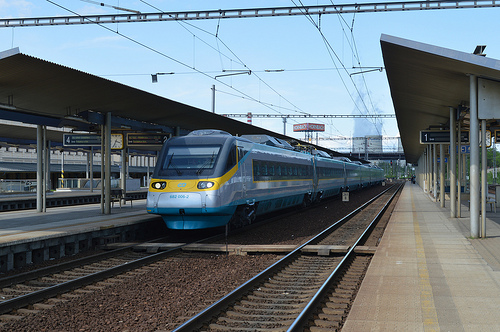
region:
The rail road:
[196, 202, 298, 317]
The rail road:
[224, 239, 308, 329]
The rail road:
[236, 291, 265, 327]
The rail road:
[227, 251, 296, 318]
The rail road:
[216, 211, 342, 307]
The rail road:
[216, 279, 266, 328]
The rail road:
[234, 280, 286, 321]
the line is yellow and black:
[421, 281, 439, 312]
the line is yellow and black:
[430, 292, 442, 329]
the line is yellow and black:
[427, 285, 439, 319]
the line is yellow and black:
[427, 287, 434, 321]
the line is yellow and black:
[417, 298, 443, 320]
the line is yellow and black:
[436, 289, 438, 319]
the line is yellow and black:
[429, 292, 441, 325]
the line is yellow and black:
[427, 304, 444, 330]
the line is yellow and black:
[441, 303, 453, 330]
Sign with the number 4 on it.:
[63, 134, 101, 146]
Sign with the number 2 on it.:
[127, 132, 171, 145]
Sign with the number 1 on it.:
[420, 130, 474, 142]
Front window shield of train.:
[157, 143, 223, 173]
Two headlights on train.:
[148, 179, 217, 189]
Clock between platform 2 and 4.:
[110, 132, 126, 148]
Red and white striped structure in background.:
[245, 112, 255, 125]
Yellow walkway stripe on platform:
[405, 182, 442, 327]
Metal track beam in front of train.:
[95, 234, 378, 252]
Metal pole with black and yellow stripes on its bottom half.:
[60, 151, 67, 189]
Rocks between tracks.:
[91, 280, 181, 330]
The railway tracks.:
[293, 216, 355, 324]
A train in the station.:
[124, 125, 386, 241]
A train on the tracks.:
[144, 120, 389, 238]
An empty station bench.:
[98, 186, 135, 217]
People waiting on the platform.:
[406, 172, 418, 187]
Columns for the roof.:
[416, 78, 498, 249]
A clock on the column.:
[108, 129, 124, 153]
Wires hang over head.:
[148, 15, 303, 127]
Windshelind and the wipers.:
[162, 140, 218, 173]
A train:
[159, 109, 341, 248]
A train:
[145, 96, 313, 240]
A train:
[193, 131, 302, 228]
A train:
[194, 76, 288, 183]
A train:
[171, 109, 255, 196]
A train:
[174, 116, 286, 246]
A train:
[176, 126, 256, 223]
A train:
[171, 136, 248, 206]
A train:
[170, 80, 288, 281]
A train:
[206, 142, 282, 214]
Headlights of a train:
[195, 180, 214, 190]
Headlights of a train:
[148, 176, 170, 193]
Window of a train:
[160, 141, 216, 168]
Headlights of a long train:
[193, 179, 215, 189]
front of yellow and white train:
[135, 136, 245, 243]